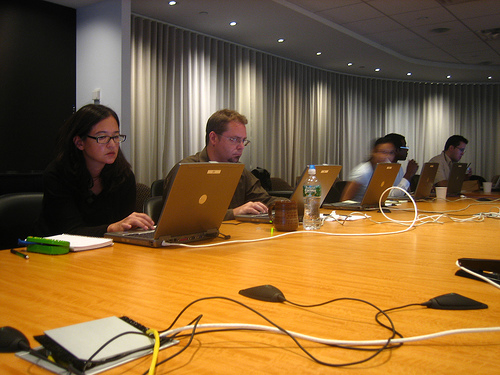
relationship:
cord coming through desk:
[153, 284, 402, 374] [3, 188, 484, 371]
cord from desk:
[144, 322, 163, 374] [3, 188, 484, 371]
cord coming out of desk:
[163, 183, 498, 249] [3, 188, 500, 375]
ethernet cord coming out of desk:
[175, 182, 494, 248] [1, 164, 498, 374]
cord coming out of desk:
[318, 189, 475, 251] [73, 134, 485, 345]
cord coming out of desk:
[144, 328, 163, 375] [3, 188, 484, 371]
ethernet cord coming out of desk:
[159, 187, 489, 250] [3, 188, 484, 371]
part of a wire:
[305, 253, 386, 297] [308, 290, 393, 317]